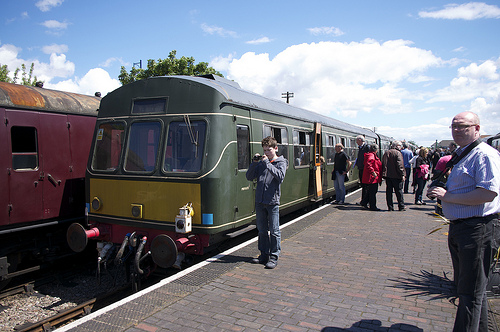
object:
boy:
[246, 136, 291, 270]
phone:
[252, 154, 263, 160]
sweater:
[246, 156, 288, 207]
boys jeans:
[255, 203, 281, 256]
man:
[426, 111, 500, 332]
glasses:
[450, 123, 477, 128]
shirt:
[439, 142, 499, 219]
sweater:
[360, 153, 380, 186]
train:
[63, 74, 396, 294]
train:
[1, 82, 86, 288]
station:
[291, 206, 444, 331]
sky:
[1, 1, 498, 52]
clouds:
[229, 40, 434, 106]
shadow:
[387, 269, 454, 304]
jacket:
[361, 151, 383, 185]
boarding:
[313, 121, 323, 201]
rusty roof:
[1, 81, 105, 119]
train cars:
[377, 131, 399, 163]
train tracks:
[0, 278, 117, 331]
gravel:
[0, 286, 26, 332]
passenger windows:
[291, 128, 312, 167]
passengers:
[331, 142, 353, 205]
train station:
[0, 1, 499, 331]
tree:
[118, 48, 225, 86]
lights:
[90, 197, 101, 211]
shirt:
[332, 151, 350, 173]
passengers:
[353, 135, 372, 206]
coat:
[382, 148, 407, 181]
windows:
[264, 124, 289, 168]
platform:
[52, 178, 500, 332]